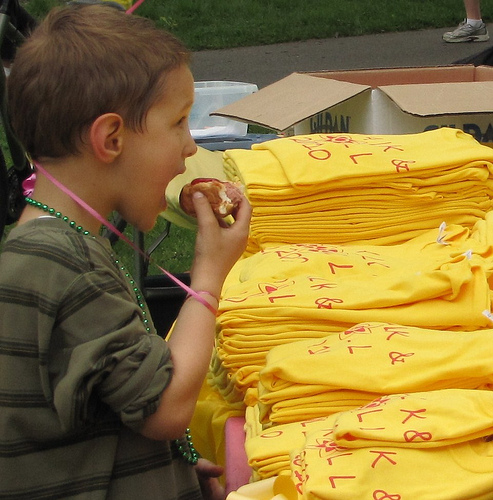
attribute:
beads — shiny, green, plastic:
[35, 213, 162, 311]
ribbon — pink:
[65, 194, 212, 317]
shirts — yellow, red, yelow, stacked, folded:
[203, 142, 483, 490]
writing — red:
[291, 243, 391, 311]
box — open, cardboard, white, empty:
[267, 65, 490, 140]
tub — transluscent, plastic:
[185, 78, 267, 140]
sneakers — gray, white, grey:
[433, 24, 492, 51]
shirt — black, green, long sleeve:
[4, 229, 180, 500]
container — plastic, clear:
[185, 78, 263, 143]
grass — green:
[159, 4, 466, 44]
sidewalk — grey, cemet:
[183, 38, 487, 87]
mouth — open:
[163, 165, 190, 208]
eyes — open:
[173, 108, 197, 132]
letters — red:
[296, 134, 338, 179]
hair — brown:
[26, 31, 148, 112]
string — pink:
[45, 165, 153, 274]